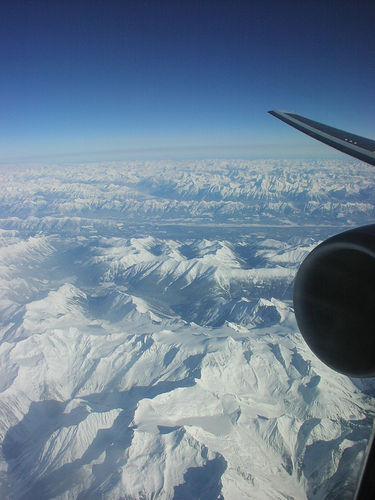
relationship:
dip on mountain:
[127, 274, 162, 304] [80, 250, 298, 335]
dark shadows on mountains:
[4, 366, 196, 457] [6, 166, 364, 497]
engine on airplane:
[292, 222, 373, 378] [265, 109, 375, 497]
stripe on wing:
[269, 109, 374, 162] [268, 108, 374, 171]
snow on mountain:
[1, 282, 201, 458] [3, 283, 202, 444]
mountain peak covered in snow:
[123, 420, 206, 447] [127, 412, 173, 428]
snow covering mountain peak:
[127, 412, 173, 428] [123, 420, 206, 447]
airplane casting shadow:
[265, 109, 375, 497] [285, 412, 372, 492]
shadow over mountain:
[285, 412, 372, 492] [66, 367, 252, 497]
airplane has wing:
[265, 107, 363, 379] [268, 108, 374, 171]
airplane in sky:
[265, 107, 363, 379] [199, 5, 363, 107]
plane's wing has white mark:
[266, 109, 362, 162] [353, 140, 359, 149]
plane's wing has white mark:
[266, 109, 362, 162] [347, 136, 357, 145]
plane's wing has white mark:
[266, 109, 362, 162] [340, 133, 348, 144]